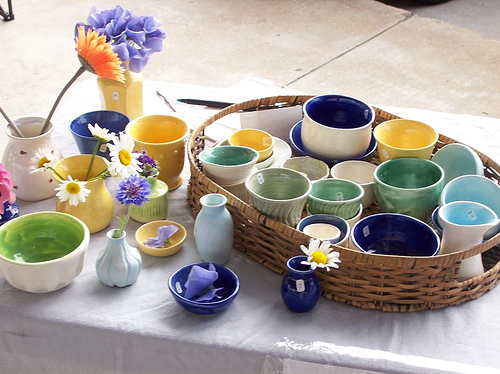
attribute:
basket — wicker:
[187, 92, 500, 313]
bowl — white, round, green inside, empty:
[1, 209, 92, 295]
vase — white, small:
[93, 225, 143, 288]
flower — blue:
[115, 175, 151, 206]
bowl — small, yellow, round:
[135, 218, 190, 259]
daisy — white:
[298, 236, 342, 273]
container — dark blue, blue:
[279, 254, 321, 314]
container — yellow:
[50, 152, 115, 236]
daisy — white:
[26, 146, 67, 174]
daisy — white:
[54, 174, 92, 207]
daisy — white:
[84, 120, 117, 145]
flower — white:
[105, 130, 145, 179]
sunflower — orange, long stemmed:
[75, 25, 128, 85]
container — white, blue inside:
[299, 92, 376, 160]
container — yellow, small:
[227, 127, 275, 163]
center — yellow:
[312, 250, 329, 263]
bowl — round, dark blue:
[168, 261, 242, 316]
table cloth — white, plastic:
[2, 71, 499, 373]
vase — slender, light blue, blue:
[193, 191, 236, 267]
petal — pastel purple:
[145, 225, 177, 248]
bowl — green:
[308, 177, 365, 221]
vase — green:
[373, 156, 445, 225]